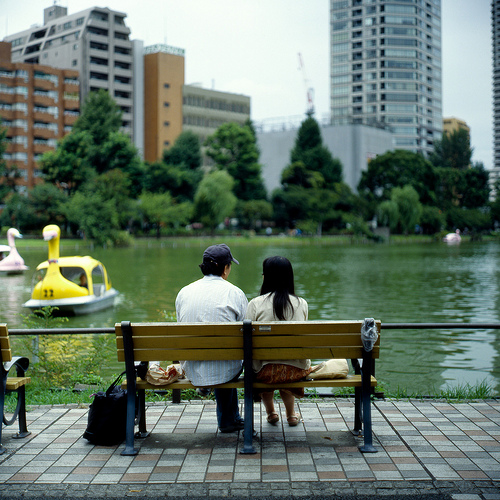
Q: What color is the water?
A: Green.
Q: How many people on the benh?
A: Two.